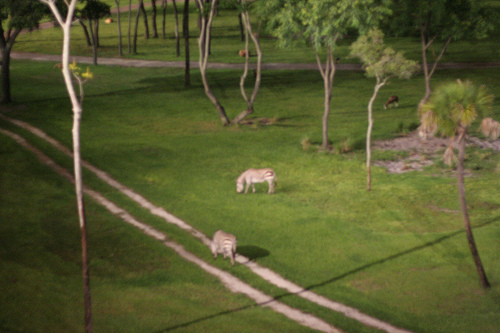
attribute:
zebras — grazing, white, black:
[197, 159, 277, 263]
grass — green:
[8, 2, 498, 332]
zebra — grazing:
[238, 162, 277, 196]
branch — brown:
[430, 34, 464, 77]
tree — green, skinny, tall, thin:
[408, 6, 492, 109]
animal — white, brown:
[382, 90, 400, 112]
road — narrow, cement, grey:
[6, 46, 499, 87]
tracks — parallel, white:
[5, 114, 411, 329]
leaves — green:
[396, 3, 489, 39]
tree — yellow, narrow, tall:
[406, 80, 499, 308]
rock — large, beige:
[101, 12, 115, 26]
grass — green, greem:
[142, 130, 180, 162]